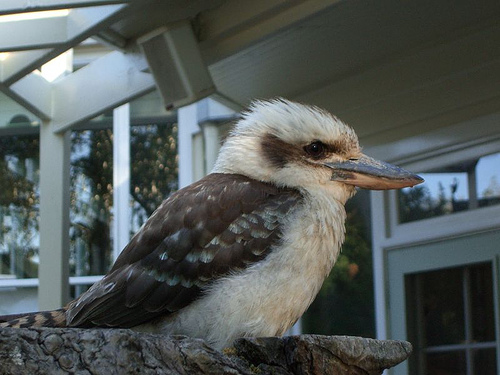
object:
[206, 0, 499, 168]
wall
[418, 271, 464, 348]
pane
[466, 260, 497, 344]
pane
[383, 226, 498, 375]
door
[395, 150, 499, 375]
window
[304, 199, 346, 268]
breast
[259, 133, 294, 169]
spot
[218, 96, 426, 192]
head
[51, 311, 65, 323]
brown feathers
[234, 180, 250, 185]
white feathers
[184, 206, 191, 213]
white feathers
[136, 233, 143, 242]
white feathers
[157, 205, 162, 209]
white feathers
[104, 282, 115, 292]
white feathers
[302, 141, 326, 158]
eye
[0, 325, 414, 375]
stone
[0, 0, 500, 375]
building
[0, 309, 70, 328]
tail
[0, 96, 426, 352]
bird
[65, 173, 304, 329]
black feathers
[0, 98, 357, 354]
feather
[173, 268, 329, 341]
underbelly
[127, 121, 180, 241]
tree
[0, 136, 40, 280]
tree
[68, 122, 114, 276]
tree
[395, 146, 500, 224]
reflection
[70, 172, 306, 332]
wing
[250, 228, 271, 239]
spot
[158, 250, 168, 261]
spot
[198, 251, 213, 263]
spot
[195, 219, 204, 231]
spot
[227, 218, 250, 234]
spot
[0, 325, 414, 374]
perch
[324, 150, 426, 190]
beak